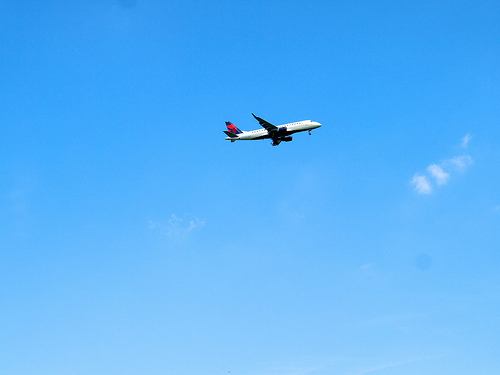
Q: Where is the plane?
A: The sky.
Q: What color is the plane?
A: White.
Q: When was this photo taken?
A: Day time.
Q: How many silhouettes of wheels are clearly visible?
A: One.